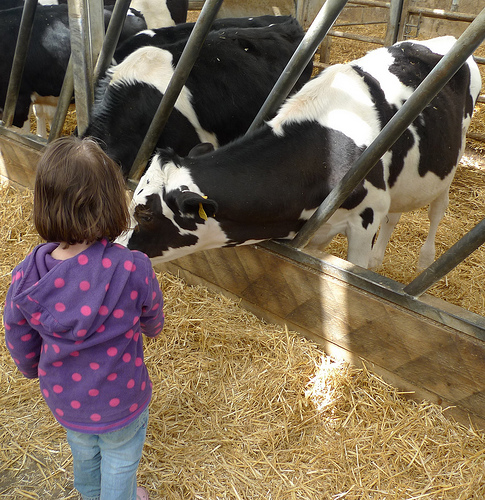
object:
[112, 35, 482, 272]
cow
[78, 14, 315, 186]
cow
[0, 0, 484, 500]
floor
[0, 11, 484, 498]
hay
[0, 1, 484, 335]
gate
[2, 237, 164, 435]
hoodie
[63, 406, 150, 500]
jeans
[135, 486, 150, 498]
shoe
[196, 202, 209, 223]
tag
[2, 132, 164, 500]
girl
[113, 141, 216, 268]
head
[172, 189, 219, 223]
ear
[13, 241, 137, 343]
hood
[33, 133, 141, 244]
hair